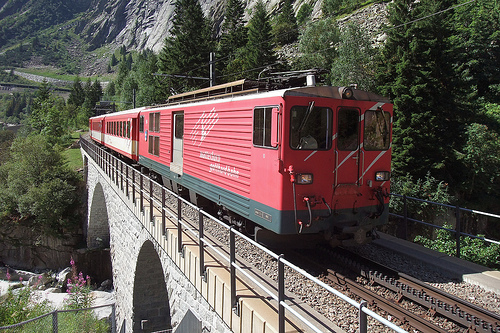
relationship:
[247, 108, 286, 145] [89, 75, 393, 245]
window of car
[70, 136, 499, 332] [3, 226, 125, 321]
bridge over gorge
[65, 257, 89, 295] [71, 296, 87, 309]
flowers on branches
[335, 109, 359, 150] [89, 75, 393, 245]
window on front of car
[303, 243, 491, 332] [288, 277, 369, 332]
tracks on gravel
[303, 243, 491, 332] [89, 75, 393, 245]
tracks of car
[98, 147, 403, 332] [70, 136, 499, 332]
railing on bridge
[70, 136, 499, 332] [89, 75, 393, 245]
bridge of car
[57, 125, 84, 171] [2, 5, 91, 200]
grass in valley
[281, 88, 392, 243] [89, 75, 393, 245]
front of car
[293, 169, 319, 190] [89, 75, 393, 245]
head light on car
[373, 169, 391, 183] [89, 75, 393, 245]
head light on car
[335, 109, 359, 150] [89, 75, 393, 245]
window on car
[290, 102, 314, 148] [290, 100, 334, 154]
wiper of windshield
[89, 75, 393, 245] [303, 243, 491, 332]
car on tracks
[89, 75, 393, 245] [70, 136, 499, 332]
car on bridge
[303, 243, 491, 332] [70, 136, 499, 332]
tracks on bridge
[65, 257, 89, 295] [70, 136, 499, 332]
flowers under bridge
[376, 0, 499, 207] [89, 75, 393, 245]
trees next to car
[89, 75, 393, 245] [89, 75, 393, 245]
car has car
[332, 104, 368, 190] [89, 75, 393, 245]
dor of car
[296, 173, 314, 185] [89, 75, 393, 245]
head light of car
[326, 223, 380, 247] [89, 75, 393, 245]
bumper of car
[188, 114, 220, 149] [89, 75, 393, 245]
logo of car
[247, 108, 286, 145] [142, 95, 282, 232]
window on side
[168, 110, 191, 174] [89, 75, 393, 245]
door of car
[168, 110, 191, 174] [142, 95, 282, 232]
door on side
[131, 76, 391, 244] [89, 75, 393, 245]
car of car